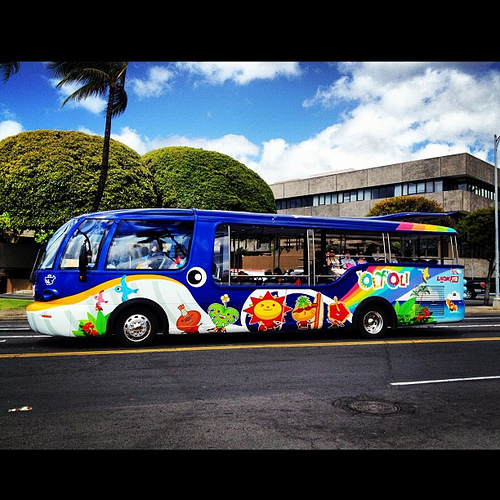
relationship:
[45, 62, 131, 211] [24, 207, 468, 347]
tree behind bus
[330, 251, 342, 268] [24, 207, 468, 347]
person on bus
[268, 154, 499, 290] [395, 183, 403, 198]
building has a window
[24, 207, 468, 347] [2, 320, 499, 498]
bus on street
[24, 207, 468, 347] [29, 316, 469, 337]
bus has a bottom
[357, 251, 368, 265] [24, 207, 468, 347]
passenger on bus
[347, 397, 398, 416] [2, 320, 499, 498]
manhole on street